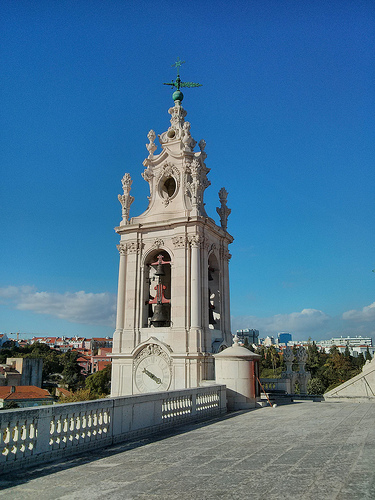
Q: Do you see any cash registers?
A: No, there are no cash registers.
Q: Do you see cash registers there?
A: No, there are no cash registers.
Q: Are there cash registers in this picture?
A: No, there are no cash registers.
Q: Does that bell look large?
A: Yes, the bell is large.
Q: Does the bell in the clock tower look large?
A: Yes, the bell is large.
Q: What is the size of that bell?
A: The bell is large.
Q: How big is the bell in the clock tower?
A: The bell is large.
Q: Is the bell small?
A: No, the bell is large.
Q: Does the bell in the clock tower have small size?
A: No, the bell is large.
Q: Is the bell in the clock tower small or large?
A: The bell is large.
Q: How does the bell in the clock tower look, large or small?
A: The bell is large.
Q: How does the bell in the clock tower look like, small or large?
A: The bell is large.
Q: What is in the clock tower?
A: The bell is in the clock tower.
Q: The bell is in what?
A: The bell is in the clock tower.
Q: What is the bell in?
A: The bell is in the clock tower.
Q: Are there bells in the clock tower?
A: Yes, there is a bell in the clock tower.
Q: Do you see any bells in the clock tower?
A: Yes, there is a bell in the clock tower.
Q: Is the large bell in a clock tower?
A: Yes, the bell is in a clock tower.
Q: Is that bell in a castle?
A: No, the bell is in a clock tower.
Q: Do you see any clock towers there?
A: Yes, there is a clock tower.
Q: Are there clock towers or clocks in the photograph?
A: Yes, there is a clock tower.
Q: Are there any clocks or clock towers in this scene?
A: Yes, there is a clock tower.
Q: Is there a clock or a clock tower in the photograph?
A: Yes, there is a clock tower.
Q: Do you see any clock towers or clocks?
A: Yes, there is a clock tower.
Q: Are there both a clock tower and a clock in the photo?
A: Yes, there are both a clock tower and a clock.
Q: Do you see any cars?
A: No, there are no cars.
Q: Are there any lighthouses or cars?
A: No, there are no cars or lighthouses.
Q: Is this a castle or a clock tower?
A: This is a clock tower.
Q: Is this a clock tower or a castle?
A: This is a clock tower.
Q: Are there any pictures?
A: No, there are no pictures.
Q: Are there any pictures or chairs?
A: No, there are no pictures or chairs.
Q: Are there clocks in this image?
A: Yes, there is a clock.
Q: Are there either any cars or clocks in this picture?
A: Yes, there is a clock.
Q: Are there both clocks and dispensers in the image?
A: No, there is a clock but no dispensers.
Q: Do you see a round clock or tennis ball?
A: Yes, there is a round clock.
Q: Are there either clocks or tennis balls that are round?
A: Yes, the clock is round.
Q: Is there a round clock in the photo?
A: Yes, there is a round clock.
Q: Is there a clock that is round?
A: Yes, there is a clock that is round.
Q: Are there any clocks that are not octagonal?
A: Yes, there is an round clock.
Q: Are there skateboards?
A: No, there are no skateboards.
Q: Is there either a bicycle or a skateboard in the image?
A: No, there are no skateboards or bicycles.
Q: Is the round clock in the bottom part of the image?
A: Yes, the clock is in the bottom of the image.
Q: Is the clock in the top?
A: No, the clock is in the bottom of the image.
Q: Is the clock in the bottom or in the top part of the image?
A: The clock is in the bottom of the image.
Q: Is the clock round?
A: Yes, the clock is round.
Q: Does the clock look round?
A: Yes, the clock is round.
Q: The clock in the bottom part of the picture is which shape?
A: The clock is round.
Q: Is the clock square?
A: No, the clock is round.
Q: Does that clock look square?
A: No, the clock is round.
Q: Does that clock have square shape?
A: No, the clock is round.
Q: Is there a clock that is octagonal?
A: No, there is a clock but it is round.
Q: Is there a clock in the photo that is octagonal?
A: No, there is a clock but it is round.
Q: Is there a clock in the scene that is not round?
A: No, there is a clock but it is round.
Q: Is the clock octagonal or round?
A: The clock is round.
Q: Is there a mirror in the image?
A: No, there are no mirrors.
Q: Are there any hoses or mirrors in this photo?
A: No, there are no mirrors or hoses.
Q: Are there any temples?
A: No, there are no temples.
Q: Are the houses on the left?
A: Yes, the houses are on the left of the image.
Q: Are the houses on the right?
A: No, the houses are on the left of the image.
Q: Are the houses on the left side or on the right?
A: The houses are on the left of the image.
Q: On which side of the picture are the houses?
A: The houses are on the left of the image.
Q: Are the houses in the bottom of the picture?
A: Yes, the houses are in the bottom of the image.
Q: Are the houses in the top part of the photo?
A: No, the houses are in the bottom of the image.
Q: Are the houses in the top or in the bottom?
A: The houses are in the bottom of the image.